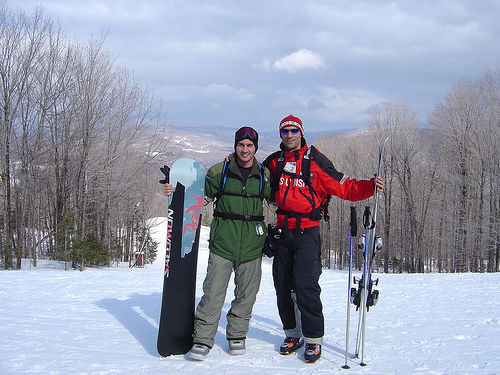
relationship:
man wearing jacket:
[262, 111, 389, 369] [262, 137, 374, 228]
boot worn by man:
[221, 335, 247, 355] [164, 126, 279, 360]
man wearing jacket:
[164, 126, 279, 360] [203, 152, 274, 263]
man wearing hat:
[262, 111, 389, 369] [274, 112, 306, 132]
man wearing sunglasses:
[262, 111, 389, 369] [277, 125, 303, 135]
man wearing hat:
[164, 126, 279, 360] [234, 125, 260, 150]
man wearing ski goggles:
[164, 126, 279, 360] [234, 128, 254, 138]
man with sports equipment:
[223, 114, 386, 361] [344, 160, 372, 363]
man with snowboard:
[223, 114, 386, 361] [155, 157, 205, 357]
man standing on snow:
[223, 114, 386, 361] [4, 266, 473, 372]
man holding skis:
[164, 126, 279, 360] [356, 136, 384, 363]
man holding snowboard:
[190, 126, 279, 363] [153, 158, 203, 362]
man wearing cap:
[164, 126, 279, 360] [276, 114, 306, 133]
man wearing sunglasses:
[223, 114, 386, 361] [281, 125, 306, 134]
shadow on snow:
[102, 293, 364, 369] [7, 261, 482, 366]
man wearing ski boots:
[262, 111, 389, 369] [276, 333, 332, 366]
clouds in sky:
[21, 8, 476, 151] [5, 7, 484, 175]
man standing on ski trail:
[164, 126, 279, 360] [43, 237, 405, 373]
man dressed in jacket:
[164, 126, 279, 360] [208, 157, 268, 256]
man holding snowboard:
[164, 126, 279, 360] [159, 151, 199, 362]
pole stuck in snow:
[340, 206, 353, 373] [7, 261, 482, 366]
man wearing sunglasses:
[223, 114, 386, 361] [282, 129, 303, 136]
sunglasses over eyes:
[282, 129, 303, 136] [285, 128, 300, 131]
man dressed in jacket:
[223, 114, 386, 361] [265, 149, 388, 228]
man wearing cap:
[223, 114, 386, 361] [276, 110, 306, 126]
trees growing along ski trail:
[403, 89, 485, 268] [0, 309, 111, 322]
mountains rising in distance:
[128, 120, 237, 165] [9, 30, 477, 206]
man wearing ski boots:
[164, 126, 279, 360] [303, 342, 321, 363]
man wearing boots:
[164, 126, 279, 360] [184, 335, 265, 361]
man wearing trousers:
[164, 126, 279, 360] [191, 251, 260, 346]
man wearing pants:
[223, 114, 386, 361] [273, 230, 323, 350]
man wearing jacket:
[190, 126, 279, 363] [205, 158, 277, 260]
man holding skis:
[223, 114, 386, 361] [355, 165, 385, 368]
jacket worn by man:
[262, 148, 374, 226] [223, 114, 386, 361]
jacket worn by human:
[175, 152, 275, 264] [166, 126, 275, 360]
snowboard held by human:
[155, 152, 213, 355] [159, 124, 280, 365]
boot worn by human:
[184, 346, 209, 366] [159, 124, 280, 365]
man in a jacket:
[223, 114, 386, 361] [262, 137, 374, 228]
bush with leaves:
[68, 226, 109, 267] [73, 230, 114, 270]